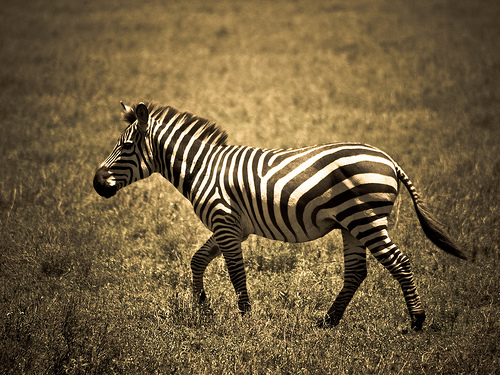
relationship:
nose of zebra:
[77, 168, 120, 199] [82, 99, 463, 344]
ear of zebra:
[113, 102, 153, 120] [82, 99, 463, 344]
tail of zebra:
[401, 165, 476, 261] [82, 99, 463, 344]